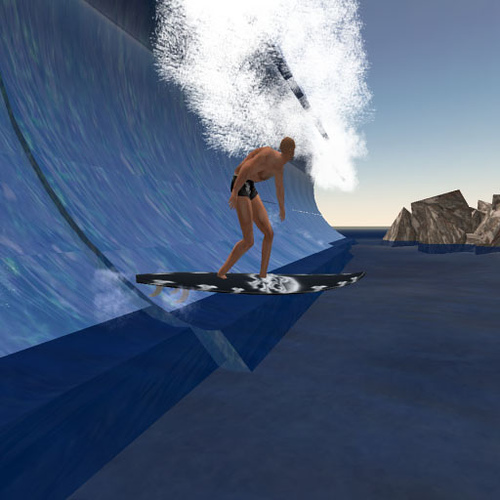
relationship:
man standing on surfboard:
[213, 136, 300, 285] [126, 258, 372, 302]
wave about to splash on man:
[150, 0, 377, 192] [213, 136, 300, 285]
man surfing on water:
[213, 136, 300, 285] [0, 224, 498, 497]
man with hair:
[213, 136, 300, 285] [266, 121, 304, 153]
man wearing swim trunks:
[213, 136, 300, 285] [229, 173, 258, 201]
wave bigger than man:
[3, 3, 383, 203] [205, 130, 301, 292]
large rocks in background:
[373, 175, 498, 268] [331, 135, 497, 263]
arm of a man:
[231, 145, 266, 210] [222, 136, 295, 275]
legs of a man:
[216, 196, 273, 274] [213, 136, 300, 285]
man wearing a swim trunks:
[213, 136, 300, 285] [229, 173, 258, 201]